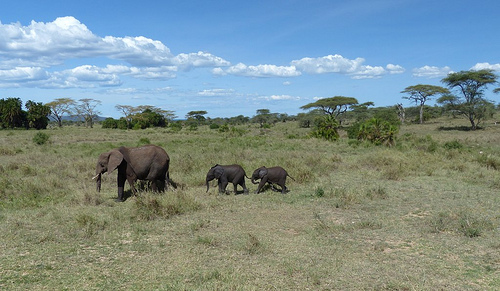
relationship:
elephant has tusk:
[93, 144, 179, 204] [94, 170, 101, 181]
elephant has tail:
[93, 144, 179, 204] [162, 160, 171, 188]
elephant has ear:
[93, 144, 179, 204] [101, 135, 130, 172]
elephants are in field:
[93, 131, 289, 211] [34, 141, 390, 272]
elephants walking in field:
[93, 131, 289, 211] [34, 141, 390, 272]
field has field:
[34, 141, 390, 272] [0, 141, 500, 272]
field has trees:
[34, 141, 390, 272] [6, 82, 497, 167]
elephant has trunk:
[93, 144, 179, 204] [93, 169, 103, 194]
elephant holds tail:
[253, 166, 290, 191] [243, 163, 249, 184]